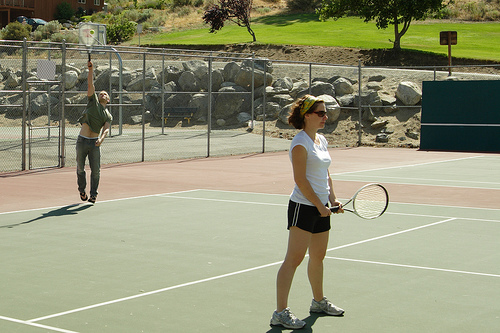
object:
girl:
[273, 93, 343, 332]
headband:
[299, 97, 318, 113]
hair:
[288, 95, 323, 129]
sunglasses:
[310, 111, 328, 117]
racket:
[330, 182, 389, 220]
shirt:
[289, 131, 333, 206]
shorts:
[287, 200, 332, 233]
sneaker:
[269, 307, 308, 329]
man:
[75, 25, 113, 203]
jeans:
[75, 135, 103, 197]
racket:
[78, 22, 97, 60]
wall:
[2, 61, 415, 125]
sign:
[440, 30, 457, 77]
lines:
[2, 188, 167, 214]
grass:
[157, 19, 499, 47]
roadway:
[0, 52, 496, 76]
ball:
[89, 30, 94, 34]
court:
[0, 146, 500, 281]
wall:
[420, 81, 500, 151]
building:
[0, 0, 103, 25]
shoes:
[269, 306, 306, 329]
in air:
[73, 190, 101, 207]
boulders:
[359, 71, 419, 120]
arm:
[85, 69, 95, 96]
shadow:
[0, 203, 94, 229]